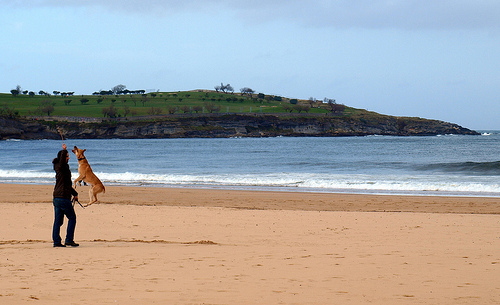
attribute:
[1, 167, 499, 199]
waves — blue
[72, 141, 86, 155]
head — brown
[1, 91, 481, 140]
hillside — brown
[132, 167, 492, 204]
wave — blue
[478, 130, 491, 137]
boat — white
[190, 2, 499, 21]
clouds — white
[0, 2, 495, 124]
sky — blue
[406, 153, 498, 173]
wave — blue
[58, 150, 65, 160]
hair — black 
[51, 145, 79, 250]
man — standing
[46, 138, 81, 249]
person — brown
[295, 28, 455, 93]
sky — blue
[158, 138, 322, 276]
sandy beach — soft, brown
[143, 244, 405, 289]
sand — brown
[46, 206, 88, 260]
jeans — denim, dark blue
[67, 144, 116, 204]
dog — brown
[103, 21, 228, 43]
clouds — white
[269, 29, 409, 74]
clouds — white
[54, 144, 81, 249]
person — brown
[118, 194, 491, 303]
sand — brown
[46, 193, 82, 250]
jeans — blue 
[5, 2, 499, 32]
cloud — white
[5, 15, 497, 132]
cloud — white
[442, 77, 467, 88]
cloud — white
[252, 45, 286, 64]
cloud — white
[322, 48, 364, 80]
cloud — white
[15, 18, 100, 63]
clouds — white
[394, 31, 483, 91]
sky — blue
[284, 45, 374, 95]
clouds — white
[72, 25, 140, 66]
sky — blue